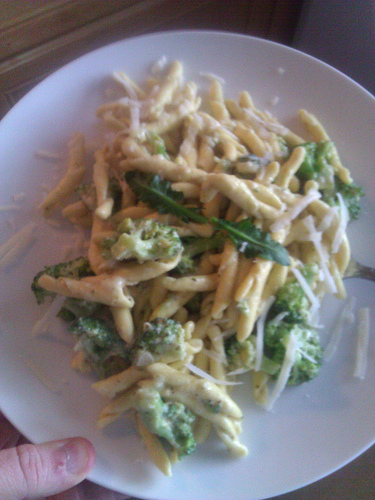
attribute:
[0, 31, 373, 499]
plate — white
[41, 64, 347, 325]
noodles — cooked, in creamy sauce, creamy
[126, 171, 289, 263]
leaves — green